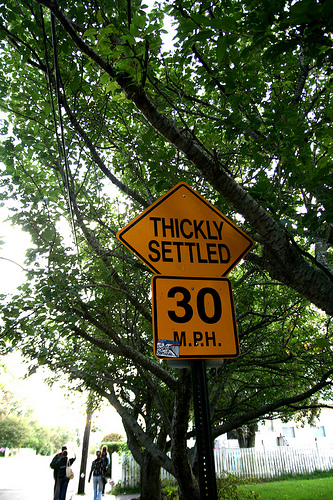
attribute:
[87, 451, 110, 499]
person — walking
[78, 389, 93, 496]
pole — brown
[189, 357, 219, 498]
pole — metal, black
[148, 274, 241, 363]
sign — orange, yellow, square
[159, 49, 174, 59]
leaf — green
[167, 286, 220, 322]
number — black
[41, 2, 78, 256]
power line — black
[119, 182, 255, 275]
sign — diamond-shaped, yellow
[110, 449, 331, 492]
fence — wooden, white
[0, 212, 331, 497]
tree — leafy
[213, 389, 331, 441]
house — white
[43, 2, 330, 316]
branch — thick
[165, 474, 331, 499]
grass — lush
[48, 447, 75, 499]
person — standing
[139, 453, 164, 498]
trunk — brown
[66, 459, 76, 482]
bag — white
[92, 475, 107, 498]
jeans — blue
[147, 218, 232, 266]
writing — black